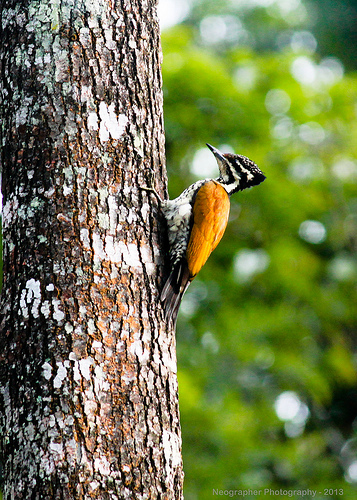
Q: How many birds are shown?
A: One.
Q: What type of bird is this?
A: Woodpecker.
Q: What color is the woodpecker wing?
A: Yellow.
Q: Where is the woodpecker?
A: On the tree.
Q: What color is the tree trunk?
A: Brown.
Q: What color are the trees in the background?
A: Green.